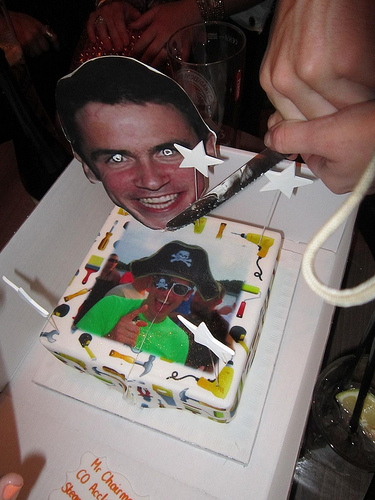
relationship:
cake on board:
[86, 217, 251, 277] [304, 199, 329, 216]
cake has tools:
[86, 217, 251, 277] [185, 158, 291, 257]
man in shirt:
[102, 295, 170, 366] [103, 301, 119, 326]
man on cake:
[102, 295, 170, 366] [86, 217, 251, 277]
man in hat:
[102, 295, 170, 366] [149, 245, 233, 305]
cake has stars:
[86, 217, 251, 277] [188, 135, 283, 207]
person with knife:
[256, 3, 374, 226] [171, 180, 248, 216]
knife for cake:
[171, 180, 248, 216] [86, 217, 251, 277]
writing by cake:
[52, 456, 125, 497] [86, 217, 251, 277]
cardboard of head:
[59, 73, 195, 222] [67, 77, 132, 136]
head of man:
[67, 77, 132, 136] [102, 295, 170, 366]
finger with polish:
[6, 472, 30, 491] [6, 484, 14, 493]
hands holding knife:
[256, 3, 374, 226] [171, 180, 248, 216]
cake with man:
[86, 217, 251, 277] [102, 295, 170, 366]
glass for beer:
[170, 43, 250, 131] [204, 34, 240, 57]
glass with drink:
[323, 360, 374, 469] [331, 393, 373, 433]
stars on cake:
[188, 135, 283, 207] [86, 217, 251, 277]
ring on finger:
[47, 30, 70, 46] [6, 472, 30, 491]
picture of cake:
[110, 243, 208, 349] [86, 217, 251, 277]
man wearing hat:
[102, 295, 170, 366] [149, 245, 233, 305]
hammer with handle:
[139, 351, 154, 379] [106, 343, 145, 370]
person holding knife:
[256, 3, 374, 226] [171, 180, 248, 216]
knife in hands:
[171, 180, 248, 216] [265, 99, 294, 157]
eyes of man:
[106, 150, 184, 156] [102, 295, 170, 366]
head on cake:
[67, 77, 132, 136] [86, 217, 251, 277]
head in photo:
[67, 77, 132, 136] [136, 240, 185, 400]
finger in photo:
[6, 472, 30, 491] [136, 240, 185, 400]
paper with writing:
[82, 458, 120, 486] [52, 456, 125, 497]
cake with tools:
[86, 217, 251, 277] [185, 158, 291, 257]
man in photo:
[102, 295, 170, 366] [136, 240, 185, 400]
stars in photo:
[188, 135, 283, 207] [136, 240, 185, 400]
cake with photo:
[86, 217, 251, 277] [136, 240, 185, 400]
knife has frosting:
[171, 180, 248, 216] [195, 173, 274, 208]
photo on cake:
[136, 240, 185, 400] [86, 217, 251, 277]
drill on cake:
[189, 375, 253, 413] [86, 217, 251, 277]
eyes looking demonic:
[106, 150, 184, 156] [99, 151, 199, 170]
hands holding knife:
[265, 99, 294, 157] [171, 180, 248, 216]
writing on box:
[52, 456, 125, 497] [160, 464, 210, 498]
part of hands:
[146, 32, 184, 64] [265, 99, 294, 157]